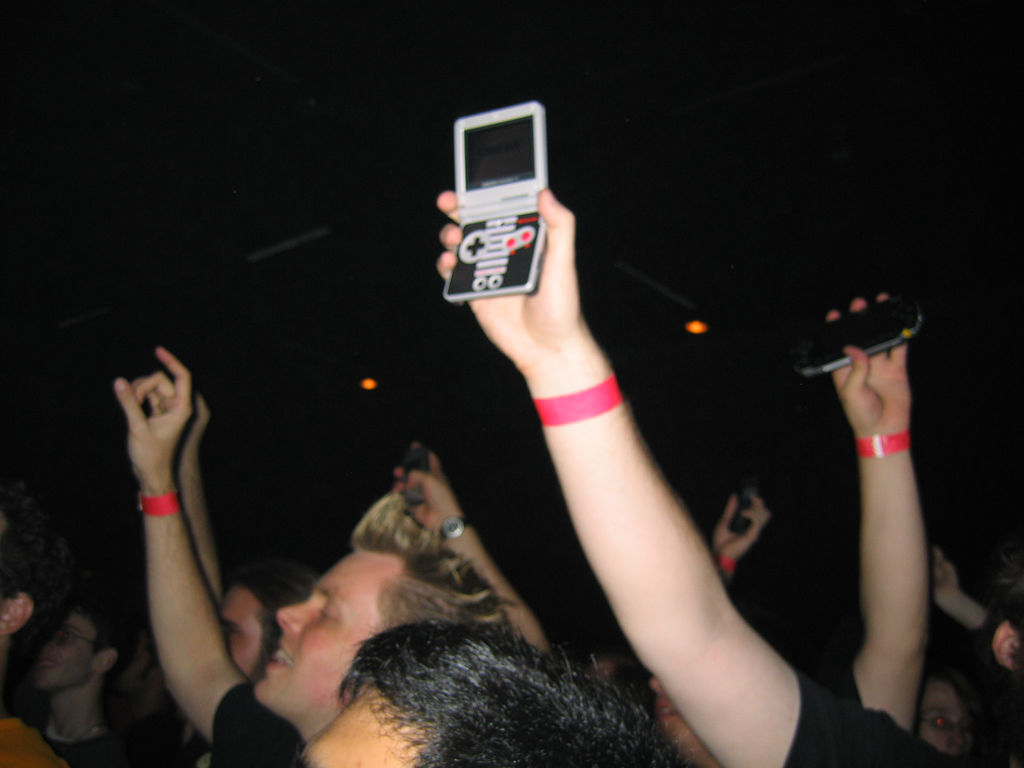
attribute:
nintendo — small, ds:
[438, 97, 556, 312]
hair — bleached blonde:
[340, 488, 512, 634]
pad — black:
[458, 235, 488, 264]